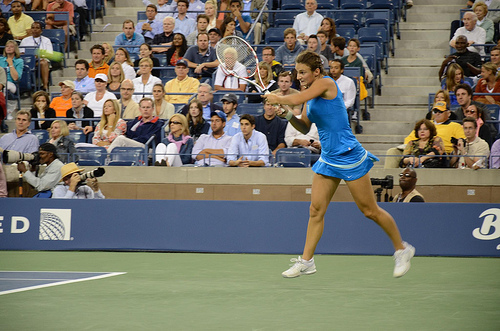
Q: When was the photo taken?
A: Daytime.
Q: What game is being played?
A: Tennis.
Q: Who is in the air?
A: Girl.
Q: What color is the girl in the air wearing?
A: Blue.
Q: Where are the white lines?
A: Tennis court.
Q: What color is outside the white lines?
A: Green.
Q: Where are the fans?
A: Stands.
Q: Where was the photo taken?
A: Near the stadium seats of a professional tennis court, in the midst of a game.